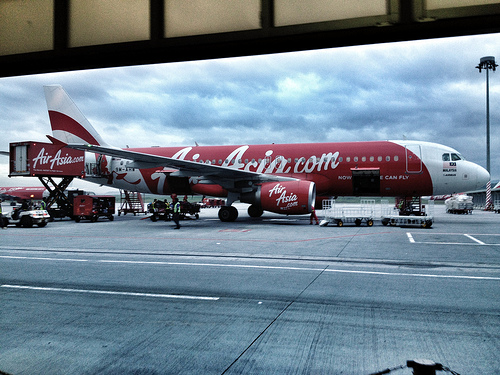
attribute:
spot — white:
[246, 301, 275, 306]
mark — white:
[204, 236, 229, 256]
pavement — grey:
[295, 281, 477, 370]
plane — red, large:
[44, 97, 497, 215]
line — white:
[21, 287, 220, 313]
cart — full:
[34, 189, 134, 230]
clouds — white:
[298, 86, 403, 138]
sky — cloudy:
[127, 27, 489, 132]